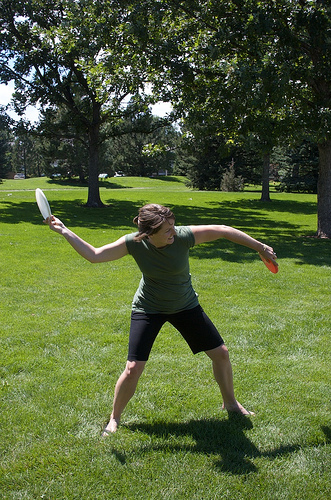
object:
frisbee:
[31, 184, 53, 222]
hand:
[42, 206, 64, 237]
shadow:
[125, 404, 331, 483]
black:
[132, 327, 148, 343]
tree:
[0, 0, 163, 216]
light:
[149, 201, 159, 208]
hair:
[132, 200, 179, 246]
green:
[159, 294, 187, 302]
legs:
[101, 322, 160, 439]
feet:
[100, 408, 124, 440]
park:
[0, 0, 331, 500]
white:
[38, 198, 49, 206]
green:
[91, 64, 103, 80]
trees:
[176, 0, 299, 204]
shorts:
[124, 303, 223, 363]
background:
[0, 5, 330, 180]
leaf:
[16, 110, 24, 115]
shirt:
[124, 226, 200, 315]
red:
[259, 255, 277, 277]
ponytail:
[133, 215, 139, 228]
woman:
[38, 180, 283, 443]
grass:
[0, 172, 331, 500]